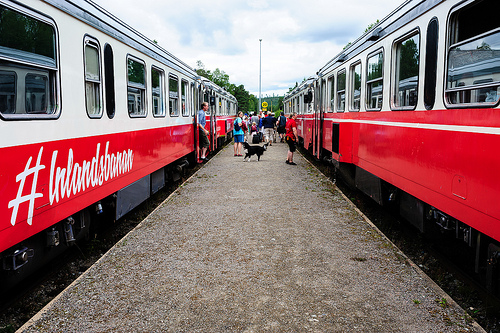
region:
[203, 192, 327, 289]
the ground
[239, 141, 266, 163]
a dog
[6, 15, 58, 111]
windows on the train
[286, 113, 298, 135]
a person wearing a red shirt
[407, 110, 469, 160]
the train is red and white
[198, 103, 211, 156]
man getting off the train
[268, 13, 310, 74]
the cloud in the sky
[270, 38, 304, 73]
the cloud is white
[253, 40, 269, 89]
a pole in the sky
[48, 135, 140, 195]
writing on the train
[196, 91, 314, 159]
people standing in between two trains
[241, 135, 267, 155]
a dog on the ground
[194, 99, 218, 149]
a man stepping off the train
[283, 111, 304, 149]
a person in a red shirt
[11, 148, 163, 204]
writing on the train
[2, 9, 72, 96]
a window of the train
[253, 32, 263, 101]
a street lamp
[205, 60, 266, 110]
large trees in the background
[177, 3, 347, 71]
a cloudy blue sky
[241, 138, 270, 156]
a black and white dog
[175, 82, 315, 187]
people at the train station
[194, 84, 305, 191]
people at the train station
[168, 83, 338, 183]
people at the train station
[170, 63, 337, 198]
people at the train station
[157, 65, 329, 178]
people at the train station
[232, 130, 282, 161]
the dog is black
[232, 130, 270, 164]
the dog is black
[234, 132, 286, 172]
the dog is black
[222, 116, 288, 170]
the dog is black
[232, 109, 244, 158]
a person standing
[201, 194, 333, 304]
the ground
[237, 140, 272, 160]
a dog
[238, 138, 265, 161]
the dog is standing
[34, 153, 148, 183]
writing on the bus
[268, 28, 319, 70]
clouds in the sky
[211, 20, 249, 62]
the clouds are white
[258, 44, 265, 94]
a pole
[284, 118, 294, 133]
a women wearing red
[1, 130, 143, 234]
logo on side of train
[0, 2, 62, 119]
passenger window on red and white train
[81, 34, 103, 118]
passenger window on red and white train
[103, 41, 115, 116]
passenger window on red and white train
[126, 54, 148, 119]
passenger window on red and white train